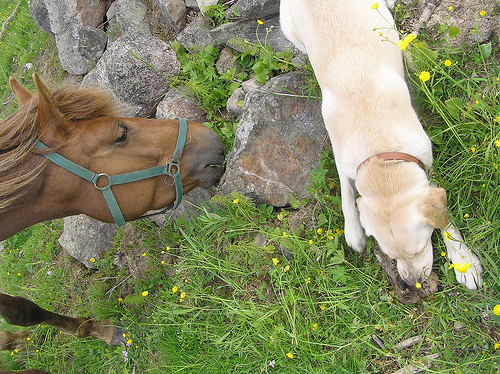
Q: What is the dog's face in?
A: Dirt.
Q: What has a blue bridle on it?
A: Horse.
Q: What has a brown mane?
A: Horse.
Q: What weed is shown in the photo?
A: Dandelion.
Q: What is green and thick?
A: Grass.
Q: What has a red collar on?
A: Dog.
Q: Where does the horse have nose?
A: Rocks.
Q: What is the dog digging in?
A: Ground.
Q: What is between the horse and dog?
A: Rocks.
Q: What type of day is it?
A: Sunny.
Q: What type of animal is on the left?
A: A horse is on the left.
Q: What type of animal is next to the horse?
A: The dog is next to the horse.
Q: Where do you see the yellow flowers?
A: You can see the yellow flowers on the right.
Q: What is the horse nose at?
A: Its on the rocks in front of the horse.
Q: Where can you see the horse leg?
A: You can see the horse's leg to the left side.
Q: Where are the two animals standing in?
A: They are standing in a grass.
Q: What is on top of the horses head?
A: The Horse has two ears on his head.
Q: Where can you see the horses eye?
A: You can see the horses eye of the right side.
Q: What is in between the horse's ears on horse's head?
A: The mane is in between the horse's ears on top of head.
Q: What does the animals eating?
A: Grass.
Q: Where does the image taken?
A: Near ground.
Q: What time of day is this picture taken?
A: Day time.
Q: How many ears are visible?
A: Four.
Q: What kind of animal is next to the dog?
A: Horse.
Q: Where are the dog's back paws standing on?
A: Rocks.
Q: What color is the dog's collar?
A: Brown.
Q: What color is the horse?
A: Brown.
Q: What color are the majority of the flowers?
A: Yellow.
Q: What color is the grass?
A: Green.